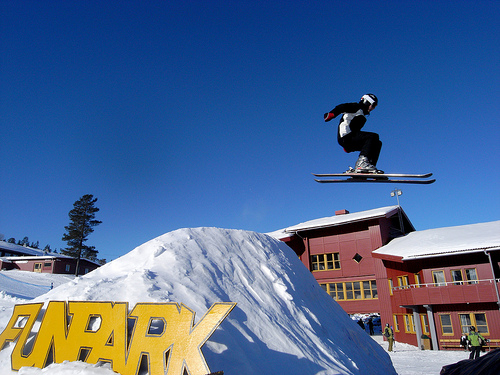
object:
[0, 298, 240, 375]
funpark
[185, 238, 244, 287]
snow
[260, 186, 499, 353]
building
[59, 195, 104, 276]
tree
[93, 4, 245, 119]
sky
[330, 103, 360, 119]
arms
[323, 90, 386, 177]
skier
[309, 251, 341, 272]
window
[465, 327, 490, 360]
people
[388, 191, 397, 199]
spotlight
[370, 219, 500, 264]
roof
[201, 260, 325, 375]
shadow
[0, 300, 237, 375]
sign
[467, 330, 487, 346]
jacket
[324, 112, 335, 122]
gloves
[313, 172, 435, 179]
skis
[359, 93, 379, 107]
helmet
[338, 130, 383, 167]
clothes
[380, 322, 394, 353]
person